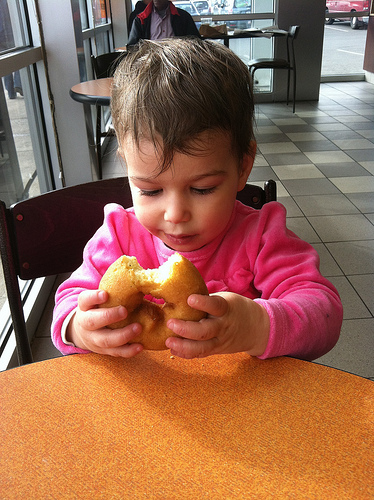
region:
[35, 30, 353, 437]
a child holding a donut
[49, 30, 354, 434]
a child in pink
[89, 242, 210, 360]
a dunot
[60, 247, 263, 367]
little hands holding a donut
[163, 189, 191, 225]
a nose of the child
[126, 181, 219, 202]
eyes of the child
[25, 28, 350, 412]
a childing sitting in front of a table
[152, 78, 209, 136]
hair of a child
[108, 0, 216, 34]
a partially seen person the background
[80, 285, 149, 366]
fingers of the child holding a donut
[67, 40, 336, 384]
Little girl eating a doughnut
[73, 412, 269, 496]
The table is speckled pattern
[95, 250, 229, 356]
Large doughnut with a bite in it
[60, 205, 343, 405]
Little girl wearing a pink shirt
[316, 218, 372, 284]
The tile has grout in between it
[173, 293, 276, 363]
The little girl has a chubby hand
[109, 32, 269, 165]
girl has short brown hair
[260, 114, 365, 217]
The tile is different colors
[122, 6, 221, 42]
Man sitting at a table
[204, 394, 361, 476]
Shadow on the table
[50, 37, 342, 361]
young girl eating a doughnut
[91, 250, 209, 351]
doughnut with bite missing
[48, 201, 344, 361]
pink long sleeve shirt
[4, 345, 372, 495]
golden brown table top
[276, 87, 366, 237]
checkered tiles on floor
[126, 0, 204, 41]
man in red and black jacket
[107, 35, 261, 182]
dark brown hair on head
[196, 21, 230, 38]
brown paper bag on table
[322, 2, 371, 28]
red pick-up truck in parking lot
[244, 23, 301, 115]
black metal chair with black cushion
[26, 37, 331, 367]
little girl sitting at the table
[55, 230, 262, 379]
child holding a donut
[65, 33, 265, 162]
the hair is brown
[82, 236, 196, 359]
the donut is light brown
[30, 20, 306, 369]
the girl is looking at the donut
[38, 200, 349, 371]
the girl`s shirt is pink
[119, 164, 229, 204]
the eyes are open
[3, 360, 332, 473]
the table is orange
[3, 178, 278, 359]
the chair is black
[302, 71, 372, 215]
the floor is grey and white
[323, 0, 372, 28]
Red truck in the parking lot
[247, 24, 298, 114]
Tall chair at the table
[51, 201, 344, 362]
Pink toddler sweater top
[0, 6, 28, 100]
Pedestrian walks on the sidewalk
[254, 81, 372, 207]
White and gray floor tile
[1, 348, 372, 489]
Orange colored table top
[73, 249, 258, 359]
Little hands grip the doughnut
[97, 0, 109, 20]
Orange sign in the window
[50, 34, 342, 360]
Toddler eats a doughnut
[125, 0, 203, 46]
Man sits a table